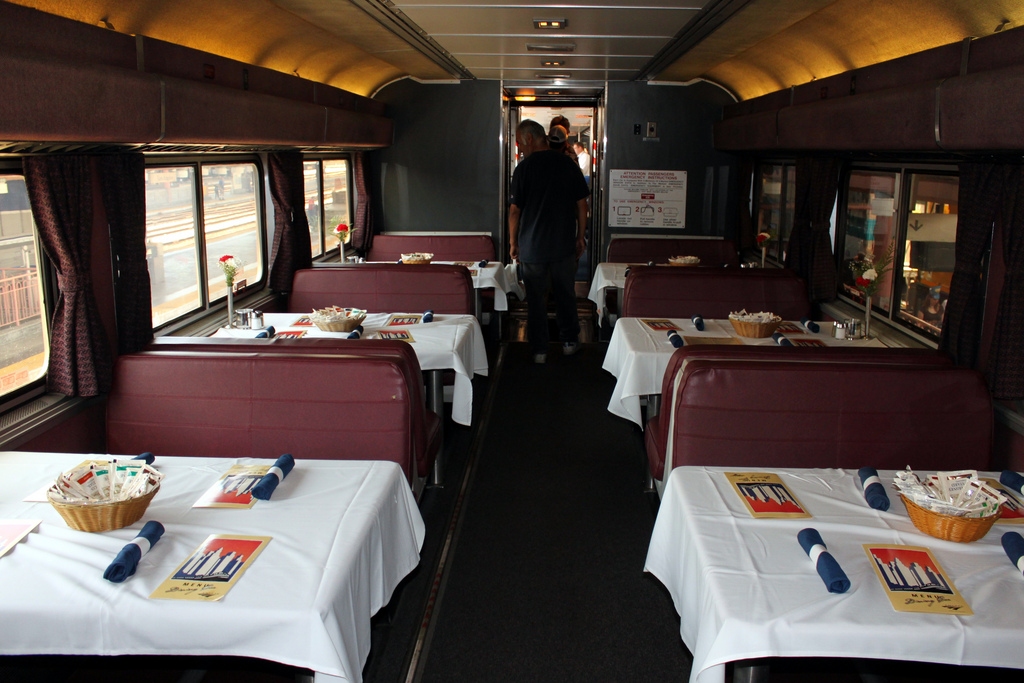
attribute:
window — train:
[2, 166, 66, 556]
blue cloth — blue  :
[101, 515, 162, 583]